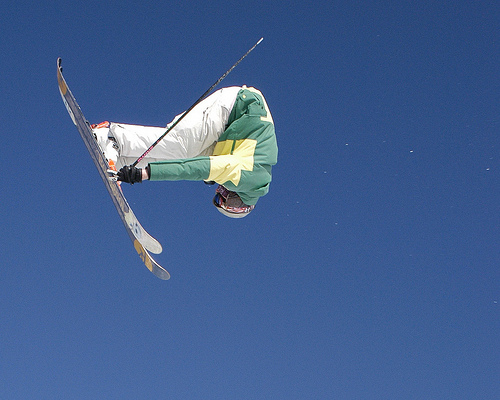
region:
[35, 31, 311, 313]
Man in the air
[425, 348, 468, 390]
Patch of pretty blue sky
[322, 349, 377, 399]
Patch of pretty blue sky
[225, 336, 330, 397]
Patch of pretty blue sky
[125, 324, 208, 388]
Patch of pretty blue sky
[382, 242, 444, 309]
Patch of pretty blue sky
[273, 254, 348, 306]
Patch of pretty blue sky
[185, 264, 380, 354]
Patch of pretty blue sky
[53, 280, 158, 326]
Patch of pretty blue sky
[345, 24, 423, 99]
Patch of pretty blue sky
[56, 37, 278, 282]
A man in the air.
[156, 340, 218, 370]
Part of the sky.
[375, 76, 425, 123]
Part of the blue sky.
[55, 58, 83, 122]
Part of a pair of skiis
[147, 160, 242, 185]
A green and yellow jacket sleeve.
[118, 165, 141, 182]
The man's black glove.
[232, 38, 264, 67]
Part of a ski pole.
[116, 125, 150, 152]
Part of the white pants.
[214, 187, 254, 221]
The man's head.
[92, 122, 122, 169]
The man's white shoe.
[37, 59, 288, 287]
kite in sky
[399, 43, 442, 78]
white clouds in blue sky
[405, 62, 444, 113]
white clouds in blue sky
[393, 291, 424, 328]
white clouds in blue sky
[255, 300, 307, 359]
white clouds in blue sky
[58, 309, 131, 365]
white clouds in blue sky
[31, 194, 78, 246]
white clouds in blue sky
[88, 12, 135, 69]
white clouds in blue sky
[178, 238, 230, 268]
white clouds in blue sky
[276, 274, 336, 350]
white clouds in blue sky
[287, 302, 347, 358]
blue sky with no clouds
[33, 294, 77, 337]
blue sky with no clouds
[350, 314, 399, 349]
blue sky with no clouds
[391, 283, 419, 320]
blue sky with no clouds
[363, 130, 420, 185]
blue sky with no clouds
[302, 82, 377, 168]
blue sky with no clouds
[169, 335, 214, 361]
blue sky with no clouds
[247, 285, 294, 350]
blue sky with no clouds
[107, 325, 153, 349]
blue sky with no clouds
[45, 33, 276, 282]
skier jumping through the air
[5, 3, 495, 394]
clear blue sky above the skier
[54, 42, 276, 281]
snow skier touching her toes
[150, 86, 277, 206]
green and yellow ski jacket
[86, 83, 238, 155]
white ski pants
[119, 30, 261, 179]
black ski pole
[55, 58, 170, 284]
a pair of skis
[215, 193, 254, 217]
the skier's helmet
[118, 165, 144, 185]
black gloves on the skier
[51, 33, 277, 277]
a skier doing a somersault